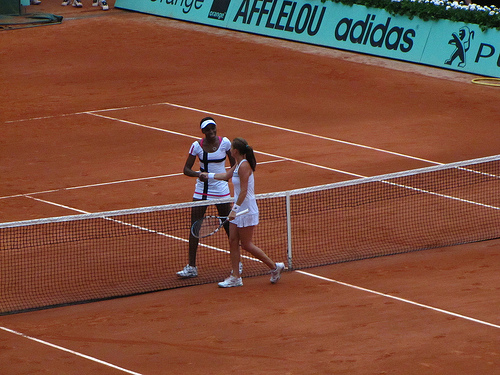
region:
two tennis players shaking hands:
[174, 113, 283, 290]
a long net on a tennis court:
[1, 153, 498, 309]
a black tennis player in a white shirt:
[179, 119, 234, 278]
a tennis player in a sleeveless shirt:
[201, 134, 288, 294]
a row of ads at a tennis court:
[110, 0, 495, 75]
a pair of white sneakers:
[217, 262, 285, 287]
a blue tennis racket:
[187, 205, 254, 235]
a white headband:
[197, 117, 215, 128]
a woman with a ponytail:
[228, 135, 261, 165]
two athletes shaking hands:
[176, 111, 285, 290]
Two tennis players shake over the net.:
[176, 116, 288, 293]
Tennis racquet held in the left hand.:
[191, 209, 248, 238]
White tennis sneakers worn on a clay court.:
[178, 258, 286, 290]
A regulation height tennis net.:
[3, 151, 499, 311]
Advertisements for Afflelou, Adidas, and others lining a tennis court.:
[127, 1, 499, 73]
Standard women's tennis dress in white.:
[187, 139, 232, 201]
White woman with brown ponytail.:
[227, 138, 259, 174]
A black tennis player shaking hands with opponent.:
[181, 117, 236, 283]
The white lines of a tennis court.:
[1, 100, 498, 373]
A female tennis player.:
[189, 138, 287, 286]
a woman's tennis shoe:
[267, 258, 287, 284]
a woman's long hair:
[230, 138, 260, 170]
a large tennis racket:
[189, 203, 253, 242]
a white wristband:
[205, 168, 218, 178]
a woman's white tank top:
[226, 158, 260, 217]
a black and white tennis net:
[0, 136, 499, 329]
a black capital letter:
[301, 6, 331, 34]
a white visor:
[196, 118, 220, 132]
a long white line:
[294, 263, 499, 334]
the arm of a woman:
[182, 140, 197, 176]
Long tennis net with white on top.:
[0, 156, 497, 318]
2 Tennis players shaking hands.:
[175, 114, 294, 291]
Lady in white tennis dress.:
[218, 129, 285, 294]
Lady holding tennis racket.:
[190, 134, 287, 292]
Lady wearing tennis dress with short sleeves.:
[179, 117, 241, 284]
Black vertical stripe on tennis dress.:
[181, 127, 234, 207]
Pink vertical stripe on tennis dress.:
[183, 114, 240, 206]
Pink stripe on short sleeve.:
[185, 137, 202, 157]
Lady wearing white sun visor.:
[174, 117, 234, 281]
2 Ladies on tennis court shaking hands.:
[0, 0, 499, 372]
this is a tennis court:
[24, 24, 464, 359]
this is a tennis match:
[4, 20, 421, 333]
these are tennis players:
[165, 119, 363, 287]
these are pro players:
[160, 109, 325, 329]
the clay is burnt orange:
[37, 44, 187, 164]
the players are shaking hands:
[140, 124, 355, 254]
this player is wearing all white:
[227, 164, 259, 221]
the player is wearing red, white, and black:
[188, 148, 222, 200]